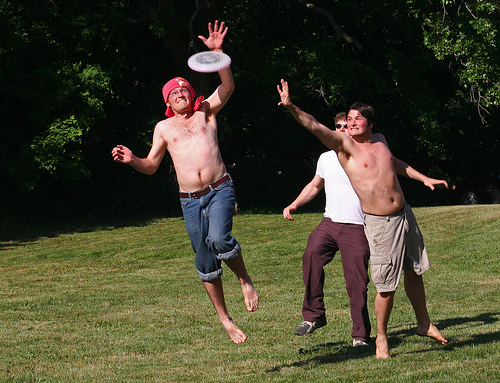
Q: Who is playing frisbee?
A: Three men.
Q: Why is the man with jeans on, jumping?
A: To catch the frisbee.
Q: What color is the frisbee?
A: White.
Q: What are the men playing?
A: Frisbee.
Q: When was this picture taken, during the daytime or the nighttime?
A: Daytime.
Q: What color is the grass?
A: Green.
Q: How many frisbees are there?
A: One.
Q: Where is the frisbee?
A: In the air.